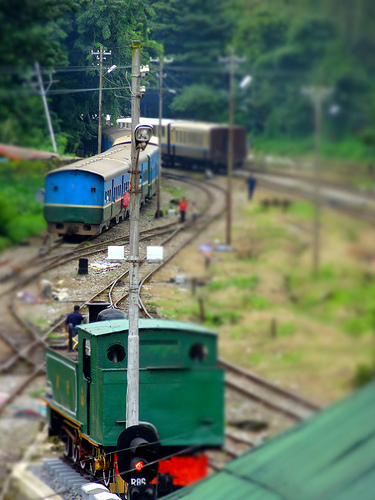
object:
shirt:
[65, 311, 85, 335]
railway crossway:
[0, 164, 375, 498]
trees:
[226, 418, 267, 432]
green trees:
[0, 0, 375, 155]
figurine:
[179, 199, 188, 222]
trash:
[17, 276, 69, 305]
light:
[134, 461, 143, 472]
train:
[80, 113, 247, 179]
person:
[65, 305, 85, 352]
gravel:
[15, 180, 207, 329]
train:
[43, 133, 159, 237]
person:
[245, 175, 255, 200]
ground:
[0, 142, 375, 499]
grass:
[144, 197, 375, 395]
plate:
[131, 477, 146, 486]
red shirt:
[179, 200, 187, 211]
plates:
[116, 425, 161, 487]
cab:
[41, 299, 225, 499]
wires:
[0, 64, 375, 97]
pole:
[125, 40, 140, 429]